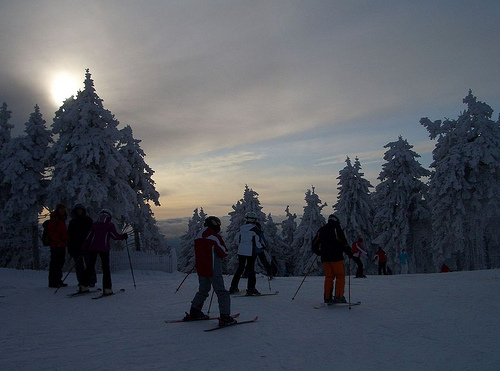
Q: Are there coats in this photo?
A: Yes, there is a coat.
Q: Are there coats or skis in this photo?
A: Yes, there is a coat.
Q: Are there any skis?
A: Yes, there are skis.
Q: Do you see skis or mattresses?
A: Yes, there are skis.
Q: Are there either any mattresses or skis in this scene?
A: Yes, there are skis.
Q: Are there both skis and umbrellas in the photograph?
A: No, there are skis but no umbrellas.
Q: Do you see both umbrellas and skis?
A: No, there are skis but no umbrellas.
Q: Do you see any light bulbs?
A: No, there are no light bulbs.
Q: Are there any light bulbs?
A: No, there are no light bulbs.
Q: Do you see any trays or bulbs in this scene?
A: No, there are no bulbs or trays.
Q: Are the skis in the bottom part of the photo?
A: Yes, the skis are in the bottom of the image.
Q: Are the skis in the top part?
A: No, the skis are in the bottom of the image.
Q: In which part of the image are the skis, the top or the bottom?
A: The skis are in the bottom of the image.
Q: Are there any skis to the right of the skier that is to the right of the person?
A: Yes, there are skis to the right of the skier.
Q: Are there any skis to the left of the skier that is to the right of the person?
A: No, the skis are to the right of the skier.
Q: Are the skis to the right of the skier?
A: Yes, the skis are to the right of the skier.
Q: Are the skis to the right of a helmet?
A: No, the skis are to the right of the skier.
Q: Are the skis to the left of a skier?
A: No, the skis are to the right of a skier.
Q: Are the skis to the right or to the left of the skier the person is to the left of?
A: The skis are to the right of the skier.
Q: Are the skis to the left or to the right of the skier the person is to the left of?
A: The skis are to the right of the skier.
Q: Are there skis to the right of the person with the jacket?
A: Yes, there are skis to the right of the person.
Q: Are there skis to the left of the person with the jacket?
A: No, the skis are to the right of the person.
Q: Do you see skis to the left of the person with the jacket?
A: No, the skis are to the right of the person.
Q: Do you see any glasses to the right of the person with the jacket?
A: No, there are skis to the right of the person.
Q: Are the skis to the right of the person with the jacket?
A: Yes, the skis are to the right of the person.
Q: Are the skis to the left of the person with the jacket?
A: No, the skis are to the right of the person.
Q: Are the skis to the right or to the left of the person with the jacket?
A: The skis are to the right of the person.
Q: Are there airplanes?
A: No, there are no airplanes.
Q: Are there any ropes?
A: No, there are no ropes.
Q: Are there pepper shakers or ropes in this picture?
A: No, there are no ropes or pepper shakers.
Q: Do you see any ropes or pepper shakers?
A: No, there are no ropes or pepper shakers.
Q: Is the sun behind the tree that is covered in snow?
A: Yes, the sun is behind the tree.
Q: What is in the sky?
A: The sun is in the sky.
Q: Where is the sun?
A: The sun is in the sky.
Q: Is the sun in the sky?
A: Yes, the sun is in the sky.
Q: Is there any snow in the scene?
A: Yes, there is snow.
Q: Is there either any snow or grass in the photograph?
A: Yes, there is snow.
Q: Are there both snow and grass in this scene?
A: No, there is snow but no grass.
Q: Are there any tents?
A: No, there are no tents.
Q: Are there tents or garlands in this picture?
A: No, there are no tents or garlands.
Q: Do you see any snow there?
A: Yes, there is snow.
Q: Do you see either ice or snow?
A: Yes, there is snow.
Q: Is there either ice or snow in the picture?
A: Yes, there is snow.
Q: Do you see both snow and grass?
A: No, there is snow but no grass.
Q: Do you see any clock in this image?
A: No, there are no clocks.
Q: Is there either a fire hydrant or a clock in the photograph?
A: No, there are no clocks or fire hydrants.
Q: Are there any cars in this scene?
A: No, there are no cars.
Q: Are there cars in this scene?
A: No, there are no cars.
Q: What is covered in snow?
A: The tree is covered in snow.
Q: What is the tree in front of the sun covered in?
A: The tree is covered in snow.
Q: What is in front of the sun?
A: The tree is in front of the sun.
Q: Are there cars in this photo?
A: No, there are no cars.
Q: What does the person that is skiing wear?
A: The person wears skis.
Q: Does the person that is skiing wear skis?
A: Yes, the person wears skis.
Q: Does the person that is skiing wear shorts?
A: No, the person wears skis.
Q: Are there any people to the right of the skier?
A: Yes, there is a person to the right of the skier.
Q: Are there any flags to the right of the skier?
A: No, there is a person to the right of the skier.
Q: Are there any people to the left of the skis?
A: Yes, there is a person to the left of the skis.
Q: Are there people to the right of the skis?
A: No, the person is to the left of the skis.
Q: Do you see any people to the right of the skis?
A: No, the person is to the left of the skis.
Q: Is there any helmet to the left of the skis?
A: No, there is a person to the left of the skis.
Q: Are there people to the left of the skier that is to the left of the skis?
A: Yes, there is a person to the left of the skier.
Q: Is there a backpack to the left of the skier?
A: No, there is a person to the left of the skier.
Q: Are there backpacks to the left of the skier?
A: No, there is a person to the left of the skier.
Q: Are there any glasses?
A: No, there are no glasses.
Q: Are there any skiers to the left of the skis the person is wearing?
A: Yes, there is a skier to the left of the skis.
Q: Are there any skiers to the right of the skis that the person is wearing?
A: No, the skier is to the left of the skis.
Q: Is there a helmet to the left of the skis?
A: No, there is a skier to the left of the skis.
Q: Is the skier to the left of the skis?
A: Yes, the skier is to the left of the skis.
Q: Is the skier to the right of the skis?
A: No, the skier is to the left of the skis.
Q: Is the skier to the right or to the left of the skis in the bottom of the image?
A: The skier is to the left of the skis.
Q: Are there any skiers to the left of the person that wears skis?
A: Yes, there is a skier to the left of the person.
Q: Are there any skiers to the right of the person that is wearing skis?
A: No, the skier is to the left of the person.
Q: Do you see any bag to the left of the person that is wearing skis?
A: No, there is a skier to the left of the person.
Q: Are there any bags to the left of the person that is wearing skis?
A: No, there is a skier to the left of the person.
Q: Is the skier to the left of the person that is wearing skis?
A: Yes, the skier is to the left of the person.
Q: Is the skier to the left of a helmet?
A: No, the skier is to the left of the person.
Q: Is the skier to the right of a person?
A: No, the skier is to the left of a person.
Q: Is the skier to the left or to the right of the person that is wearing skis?
A: The skier is to the left of the person.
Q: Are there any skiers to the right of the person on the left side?
A: Yes, there is a skier to the right of the person.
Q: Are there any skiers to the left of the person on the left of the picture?
A: No, the skier is to the right of the person.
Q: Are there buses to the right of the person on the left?
A: No, there is a skier to the right of the person.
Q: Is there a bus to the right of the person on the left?
A: No, there is a skier to the right of the person.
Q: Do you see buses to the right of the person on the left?
A: No, there is a skier to the right of the person.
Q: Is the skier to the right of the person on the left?
A: Yes, the skier is to the right of the person.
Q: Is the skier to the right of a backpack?
A: No, the skier is to the right of the person.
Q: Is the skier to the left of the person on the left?
A: No, the skier is to the right of the person.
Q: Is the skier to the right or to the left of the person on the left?
A: The skier is to the right of the person.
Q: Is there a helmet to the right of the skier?
A: No, there is a person to the right of the skier.